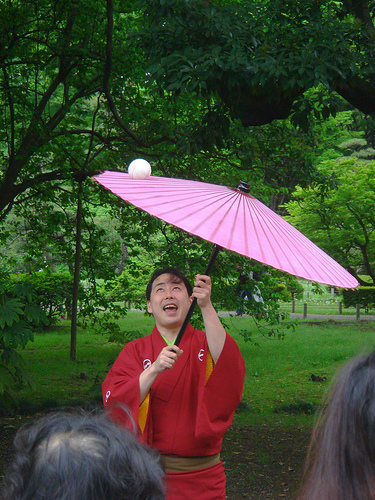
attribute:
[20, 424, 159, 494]
hair — black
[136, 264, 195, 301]
hair — short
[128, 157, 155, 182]
baseball — balanced, white, round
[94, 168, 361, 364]
umbrella — parasol, pink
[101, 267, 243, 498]
person — dressed in red, balancing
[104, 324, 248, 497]
outfit — red, robe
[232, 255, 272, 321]
people — walking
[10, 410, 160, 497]
man — balding, black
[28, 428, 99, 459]
bald spot — top of head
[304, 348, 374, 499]
woman — watching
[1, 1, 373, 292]
trees — background, all over, green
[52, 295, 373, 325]
sidewalk — long, walkway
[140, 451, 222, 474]
sash — brown, beige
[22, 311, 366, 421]
grass — green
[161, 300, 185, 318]
mouth — open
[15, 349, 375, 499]
people — watching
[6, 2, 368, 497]
park — green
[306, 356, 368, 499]
hair — brown, long